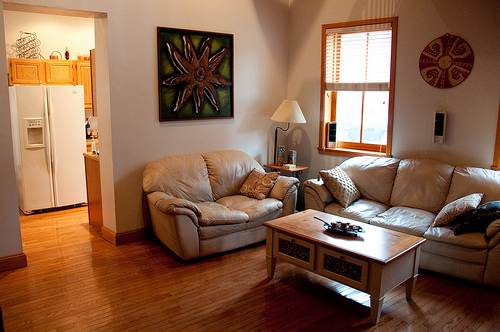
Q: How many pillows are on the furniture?
A: Four.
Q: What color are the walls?
A: White.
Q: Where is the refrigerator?
A: In the kitchen.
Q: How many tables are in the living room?
A: Two.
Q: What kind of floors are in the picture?
A: Wood.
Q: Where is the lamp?
A: In the corner.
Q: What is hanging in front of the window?
A: Blinds.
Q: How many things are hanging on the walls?
A: Three.